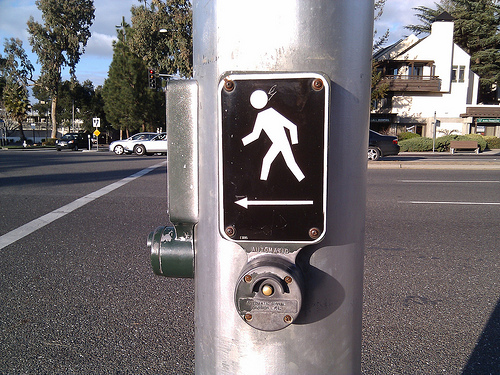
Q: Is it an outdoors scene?
A: Yes, it is outdoors.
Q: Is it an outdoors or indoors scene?
A: It is outdoors.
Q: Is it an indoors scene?
A: No, it is outdoors.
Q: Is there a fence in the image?
A: No, there are no fences.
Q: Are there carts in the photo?
A: No, there are no carts.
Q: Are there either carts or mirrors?
A: No, there are no carts or mirrors.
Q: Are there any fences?
A: No, there are no fences.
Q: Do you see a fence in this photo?
A: No, there are no fences.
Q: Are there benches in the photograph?
A: Yes, there is a bench.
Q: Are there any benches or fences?
A: Yes, there is a bench.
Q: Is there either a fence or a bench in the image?
A: Yes, there is a bench.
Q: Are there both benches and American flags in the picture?
A: No, there is a bench but no American flags.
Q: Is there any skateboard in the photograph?
A: No, there are no skateboards.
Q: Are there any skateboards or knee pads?
A: No, there are no skateboards or knee pads.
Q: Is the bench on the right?
A: Yes, the bench is on the right of the image.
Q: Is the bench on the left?
A: No, the bench is on the right of the image.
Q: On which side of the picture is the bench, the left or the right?
A: The bench is on the right of the image.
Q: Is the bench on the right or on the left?
A: The bench is on the right of the image.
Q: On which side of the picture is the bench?
A: The bench is on the right of the image.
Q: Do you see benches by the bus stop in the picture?
A: Yes, there is a bench by the bus stop.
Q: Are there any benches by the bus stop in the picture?
A: Yes, there is a bench by the bus stop.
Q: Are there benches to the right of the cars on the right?
A: Yes, there is a bench to the right of the cars.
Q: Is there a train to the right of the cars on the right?
A: No, there is a bench to the right of the cars.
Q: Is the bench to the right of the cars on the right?
A: Yes, the bench is to the right of the cars.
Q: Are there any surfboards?
A: No, there are no surfboards.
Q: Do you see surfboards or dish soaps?
A: No, there are no surfboards or dish soaps.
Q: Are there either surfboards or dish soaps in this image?
A: No, there are no surfboards or dish soaps.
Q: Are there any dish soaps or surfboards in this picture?
A: No, there are no surfboards or dish soaps.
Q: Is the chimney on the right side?
A: Yes, the chimney is on the right of the image.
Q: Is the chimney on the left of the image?
A: No, the chimney is on the right of the image.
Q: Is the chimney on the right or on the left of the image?
A: The chimney is on the right of the image.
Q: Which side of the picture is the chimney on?
A: The chimney is on the right of the image.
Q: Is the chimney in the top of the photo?
A: Yes, the chimney is in the top of the image.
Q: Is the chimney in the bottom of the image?
A: No, the chimney is in the top of the image.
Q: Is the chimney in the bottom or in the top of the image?
A: The chimney is in the top of the image.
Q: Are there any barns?
A: No, there are no barns.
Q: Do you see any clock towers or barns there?
A: No, there are no barns or clock towers.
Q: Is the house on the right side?
A: Yes, the house is on the right of the image.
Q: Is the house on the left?
A: No, the house is on the right of the image.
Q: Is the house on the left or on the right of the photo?
A: The house is on the right of the image.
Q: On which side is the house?
A: The house is on the right of the image.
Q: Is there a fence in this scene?
A: No, there are no fences.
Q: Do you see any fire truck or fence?
A: No, there are no fences or fire trucks.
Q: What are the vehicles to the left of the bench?
A: The vehicles are cars.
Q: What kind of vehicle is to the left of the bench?
A: The vehicles are cars.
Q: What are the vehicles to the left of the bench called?
A: The vehicles are cars.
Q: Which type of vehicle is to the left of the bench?
A: The vehicles are cars.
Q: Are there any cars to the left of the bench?
A: Yes, there are cars to the left of the bench.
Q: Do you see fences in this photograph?
A: No, there are no fences.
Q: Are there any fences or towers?
A: No, there are no fences or towers.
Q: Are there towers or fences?
A: No, there are no fences or towers.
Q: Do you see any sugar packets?
A: No, there are no sugar packets.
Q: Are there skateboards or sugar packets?
A: No, there are no sugar packets or skateboards.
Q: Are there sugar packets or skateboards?
A: No, there are no sugar packets or skateboards.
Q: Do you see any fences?
A: No, there are no fences.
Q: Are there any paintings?
A: No, there are no paintings.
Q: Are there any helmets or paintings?
A: No, there are no paintings or helmets.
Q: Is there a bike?
A: No, there are no bikes.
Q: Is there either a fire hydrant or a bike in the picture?
A: No, there are no bikes or fire hydrants.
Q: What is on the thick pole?
A: The symbol is on the pole.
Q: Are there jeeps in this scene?
A: No, there are no jeeps.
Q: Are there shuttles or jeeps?
A: No, there are no jeeps or shuttles.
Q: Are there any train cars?
A: No, there are no train cars.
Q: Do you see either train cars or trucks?
A: No, there are no train cars or trucks.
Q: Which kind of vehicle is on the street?
A: The vehicle is a car.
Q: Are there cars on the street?
A: Yes, there is a car on the street.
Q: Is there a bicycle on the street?
A: No, there is a car on the street.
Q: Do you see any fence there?
A: No, there are no fences.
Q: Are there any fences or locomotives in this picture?
A: No, there are no fences or locomotives.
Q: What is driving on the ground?
A: The car is driving on the ground.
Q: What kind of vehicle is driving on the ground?
A: The vehicle is a car.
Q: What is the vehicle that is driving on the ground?
A: The vehicle is a car.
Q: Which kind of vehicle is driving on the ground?
A: The vehicle is a car.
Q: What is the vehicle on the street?
A: The vehicle is a car.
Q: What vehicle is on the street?
A: The vehicle is a car.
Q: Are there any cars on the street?
A: Yes, there is a car on the street.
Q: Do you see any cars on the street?
A: Yes, there is a car on the street.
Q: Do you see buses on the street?
A: No, there is a car on the street.